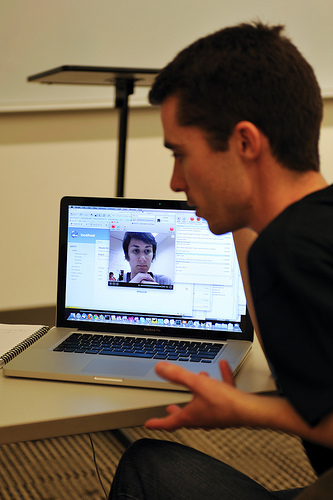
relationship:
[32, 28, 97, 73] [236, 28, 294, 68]
wall inside house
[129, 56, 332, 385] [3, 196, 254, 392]
man in front of laptop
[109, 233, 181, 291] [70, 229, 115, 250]
person on skype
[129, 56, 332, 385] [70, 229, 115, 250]
man talking on skype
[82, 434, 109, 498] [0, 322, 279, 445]
wire underneath desk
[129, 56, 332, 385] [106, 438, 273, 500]
man wearing jeans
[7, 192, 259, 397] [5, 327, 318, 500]
laptop on top of desk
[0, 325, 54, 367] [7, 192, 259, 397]
notebook next to laptop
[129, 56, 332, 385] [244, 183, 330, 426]
man wearing shirt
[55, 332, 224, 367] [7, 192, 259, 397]
keys are on top of laptop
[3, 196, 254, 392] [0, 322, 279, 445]
laptop on top of desk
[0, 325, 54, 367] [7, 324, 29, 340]
notebook has notes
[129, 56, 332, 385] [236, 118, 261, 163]
man has a ear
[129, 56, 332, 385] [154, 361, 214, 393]
man has a thumb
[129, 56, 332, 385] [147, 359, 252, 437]
man has a hand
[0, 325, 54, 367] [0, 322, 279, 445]
notebook on top of desk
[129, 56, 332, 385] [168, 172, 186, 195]
man has a nose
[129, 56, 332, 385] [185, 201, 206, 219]
man has a mouth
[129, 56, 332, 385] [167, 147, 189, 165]
man has a eye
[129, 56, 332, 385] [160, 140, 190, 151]
man has an eyebrow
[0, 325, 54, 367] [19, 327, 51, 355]
notebook has binding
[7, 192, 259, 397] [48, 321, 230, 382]
laptop has a keyboard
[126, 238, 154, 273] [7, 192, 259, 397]
face on a laptop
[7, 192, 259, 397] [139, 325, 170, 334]
laptop has a logo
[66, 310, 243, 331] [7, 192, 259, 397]
taskbar icons on a laptop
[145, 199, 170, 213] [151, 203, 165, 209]
camera has light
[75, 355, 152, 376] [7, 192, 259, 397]
touch pad on top of laptop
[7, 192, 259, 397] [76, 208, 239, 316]
laptop has a screen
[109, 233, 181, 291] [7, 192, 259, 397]
woman on laptop